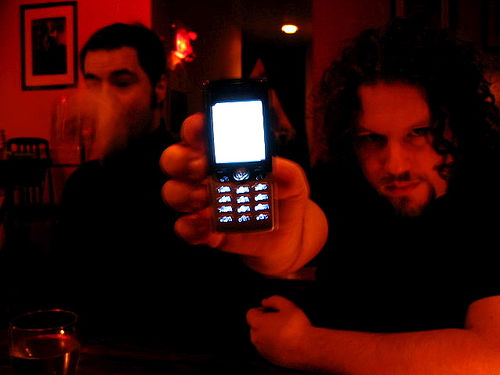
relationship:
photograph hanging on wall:
[30, 15, 66, 75] [3, 5, 149, 167]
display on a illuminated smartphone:
[210, 98, 265, 163] [199, 75, 280, 238]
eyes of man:
[357, 125, 434, 147] [159, 40, 497, 373]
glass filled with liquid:
[7, 303, 85, 373] [23, 331, 71, 373]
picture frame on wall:
[16, 2, 81, 96] [3, 5, 149, 167]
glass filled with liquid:
[7, 307, 86, 372] [4, 332, 77, 375]